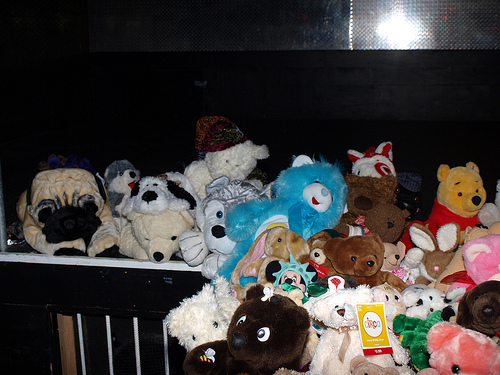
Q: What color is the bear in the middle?
A: Blue.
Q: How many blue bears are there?
A: One.